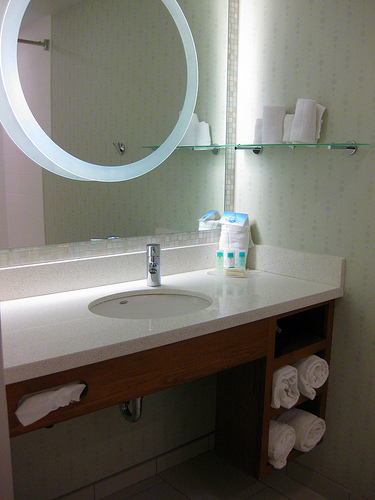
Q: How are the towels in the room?
A: Rolled.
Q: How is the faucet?
A: Off center.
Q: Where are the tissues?
A: Under the counter.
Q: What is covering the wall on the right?
A: Wallpaper.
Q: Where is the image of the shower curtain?
A: Reflected on the mirror.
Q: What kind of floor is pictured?
A: A tiled floor.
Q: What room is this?
A: Bathroom.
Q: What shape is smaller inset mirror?
A: Circle.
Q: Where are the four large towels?
A: Cubby under the counter.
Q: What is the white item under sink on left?
A: Tissue box.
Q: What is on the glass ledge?
A: Towels.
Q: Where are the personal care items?
A: Tray on counter.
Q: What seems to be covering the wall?
A: Wallpaper.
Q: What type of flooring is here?
A: Tiles.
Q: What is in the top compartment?
A: Nothing.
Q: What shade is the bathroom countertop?
A: White.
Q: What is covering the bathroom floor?
A: Tiles.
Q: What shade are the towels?
A: White.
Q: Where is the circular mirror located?
A: On the larger mirror.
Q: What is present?
A: A sink.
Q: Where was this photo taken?
A: In a bathroom.